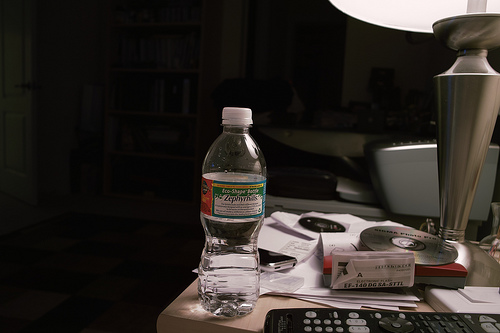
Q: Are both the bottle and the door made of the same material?
A: No, the bottle is made of plastic and the door is made of wood.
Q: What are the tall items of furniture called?
A: The pieces of furniture are shelves.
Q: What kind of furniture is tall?
A: The furniture is shelves.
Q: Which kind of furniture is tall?
A: The furniture is shelves.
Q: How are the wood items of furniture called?
A: The pieces of furniture are shelves.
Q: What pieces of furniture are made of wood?
A: The pieces of furniture are shelves.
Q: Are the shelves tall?
A: Yes, the shelves are tall.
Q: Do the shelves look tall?
A: Yes, the shelves are tall.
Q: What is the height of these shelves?
A: The shelves are tall.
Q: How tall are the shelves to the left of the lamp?
A: The shelves are tall.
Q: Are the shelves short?
A: No, the shelves are tall.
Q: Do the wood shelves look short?
A: No, the shelves are tall.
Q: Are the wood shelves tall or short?
A: The shelves are tall.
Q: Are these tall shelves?
A: Yes, these are tall shelves.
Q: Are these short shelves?
A: No, these are tall shelves.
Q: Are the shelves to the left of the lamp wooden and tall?
A: Yes, the shelves are wooden and tall.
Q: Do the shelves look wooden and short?
A: No, the shelves are wooden but tall.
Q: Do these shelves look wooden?
A: Yes, the shelves are wooden.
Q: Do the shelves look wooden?
A: Yes, the shelves are wooden.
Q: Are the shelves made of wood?
A: Yes, the shelves are made of wood.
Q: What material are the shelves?
A: The shelves are made of wood.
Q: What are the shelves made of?
A: The shelves are made of wood.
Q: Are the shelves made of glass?
A: No, the shelves are made of wood.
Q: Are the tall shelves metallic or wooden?
A: The shelves are wooden.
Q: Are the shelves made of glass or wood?
A: The shelves are made of wood.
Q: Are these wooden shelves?
A: Yes, these are wooden shelves.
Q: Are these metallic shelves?
A: No, these are wooden shelves.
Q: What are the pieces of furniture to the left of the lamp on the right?
A: The pieces of furniture are shelves.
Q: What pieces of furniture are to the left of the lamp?
A: The pieces of furniture are shelves.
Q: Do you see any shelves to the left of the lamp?
A: Yes, there are shelves to the left of the lamp.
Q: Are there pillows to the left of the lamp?
A: No, there are shelves to the left of the lamp.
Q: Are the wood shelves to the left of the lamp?
A: Yes, the shelves are to the left of the lamp.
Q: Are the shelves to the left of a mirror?
A: No, the shelves are to the left of the lamp.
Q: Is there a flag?
A: No, there are no flags.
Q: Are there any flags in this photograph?
A: No, there are no flags.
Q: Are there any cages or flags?
A: No, there are no flags or cages.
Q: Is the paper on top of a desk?
A: Yes, the paper is on top of a desk.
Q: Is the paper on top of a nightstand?
A: No, the paper is on top of a desk.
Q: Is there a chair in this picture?
A: No, there are no chairs.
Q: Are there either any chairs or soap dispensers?
A: No, there are no chairs or soap dispensers.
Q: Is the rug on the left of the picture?
A: Yes, the rug is on the left of the image.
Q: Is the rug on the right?
A: No, the rug is on the left of the image.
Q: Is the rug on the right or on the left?
A: The rug is on the left of the image.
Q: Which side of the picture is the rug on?
A: The rug is on the left of the image.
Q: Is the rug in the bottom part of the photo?
A: Yes, the rug is in the bottom of the image.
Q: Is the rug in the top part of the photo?
A: No, the rug is in the bottom of the image.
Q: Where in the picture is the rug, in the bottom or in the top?
A: The rug is in the bottom of the image.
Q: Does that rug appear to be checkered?
A: Yes, the rug is checkered.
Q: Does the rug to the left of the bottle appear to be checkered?
A: Yes, the rug is checkered.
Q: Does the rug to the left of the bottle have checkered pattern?
A: Yes, the rug is checkered.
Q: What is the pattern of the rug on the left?
A: The rug is checkered.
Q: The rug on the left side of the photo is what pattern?
A: The rug is checkered.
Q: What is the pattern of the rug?
A: The rug is checkered.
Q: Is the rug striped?
A: No, the rug is checkered.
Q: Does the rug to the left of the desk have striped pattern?
A: No, the rug is checkered.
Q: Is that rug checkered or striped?
A: The rug is checkered.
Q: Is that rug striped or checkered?
A: The rug is checkered.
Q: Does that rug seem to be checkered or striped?
A: The rug is checkered.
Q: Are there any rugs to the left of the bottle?
A: Yes, there is a rug to the left of the bottle.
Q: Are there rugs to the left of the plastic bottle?
A: Yes, there is a rug to the left of the bottle.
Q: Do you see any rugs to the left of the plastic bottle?
A: Yes, there is a rug to the left of the bottle.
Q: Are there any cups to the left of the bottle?
A: No, there is a rug to the left of the bottle.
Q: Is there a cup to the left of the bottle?
A: No, there is a rug to the left of the bottle.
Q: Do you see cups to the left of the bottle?
A: No, there is a rug to the left of the bottle.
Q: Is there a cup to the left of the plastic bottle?
A: No, there is a rug to the left of the bottle.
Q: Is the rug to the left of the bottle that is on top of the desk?
A: Yes, the rug is to the left of the bottle.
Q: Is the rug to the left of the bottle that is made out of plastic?
A: Yes, the rug is to the left of the bottle.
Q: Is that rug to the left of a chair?
A: No, the rug is to the left of the bottle.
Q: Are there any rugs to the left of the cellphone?
A: Yes, there is a rug to the left of the cellphone.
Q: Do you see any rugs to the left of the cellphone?
A: Yes, there is a rug to the left of the cellphone.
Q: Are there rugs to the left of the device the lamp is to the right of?
A: Yes, there is a rug to the left of the cellphone.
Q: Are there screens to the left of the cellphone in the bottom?
A: No, there is a rug to the left of the mobile phone.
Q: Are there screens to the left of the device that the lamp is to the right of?
A: No, there is a rug to the left of the mobile phone.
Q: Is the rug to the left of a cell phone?
A: Yes, the rug is to the left of a cell phone.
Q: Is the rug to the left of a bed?
A: No, the rug is to the left of a cell phone.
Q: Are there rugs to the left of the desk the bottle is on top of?
A: Yes, there is a rug to the left of the desk.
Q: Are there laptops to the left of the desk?
A: No, there is a rug to the left of the desk.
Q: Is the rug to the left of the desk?
A: Yes, the rug is to the left of the desk.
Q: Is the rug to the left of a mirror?
A: No, the rug is to the left of the desk.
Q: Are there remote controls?
A: Yes, there is a remote control.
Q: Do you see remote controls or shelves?
A: Yes, there is a remote control.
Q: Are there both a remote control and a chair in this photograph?
A: No, there is a remote control but no chairs.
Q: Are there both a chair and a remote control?
A: No, there is a remote control but no chairs.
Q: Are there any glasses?
A: No, there are no glasses.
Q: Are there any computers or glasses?
A: No, there are no glasses or computers.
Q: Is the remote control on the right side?
A: Yes, the remote control is on the right of the image.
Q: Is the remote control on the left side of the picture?
A: No, the remote control is on the right of the image.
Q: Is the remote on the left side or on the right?
A: The remote is on the right of the image.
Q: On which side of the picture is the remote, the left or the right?
A: The remote is on the right of the image.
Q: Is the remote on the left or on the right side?
A: The remote is on the right of the image.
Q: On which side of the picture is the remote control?
A: The remote control is on the right of the image.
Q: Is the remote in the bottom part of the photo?
A: Yes, the remote is in the bottom of the image.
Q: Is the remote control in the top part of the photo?
A: No, the remote control is in the bottom of the image.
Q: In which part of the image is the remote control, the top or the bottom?
A: The remote control is in the bottom of the image.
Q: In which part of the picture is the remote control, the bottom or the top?
A: The remote control is in the bottom of the image.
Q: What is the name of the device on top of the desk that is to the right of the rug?
A: The device is a remote control.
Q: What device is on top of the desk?
A: The device is a remote control.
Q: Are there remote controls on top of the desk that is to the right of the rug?
A: Yes, there is a remote control on top of the desk.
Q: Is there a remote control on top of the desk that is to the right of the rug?
A: Yes, there is a remote control on top of the desk.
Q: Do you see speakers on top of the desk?
A: No, there is a remote control on top of the desk.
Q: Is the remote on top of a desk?
A: Yes, the remote is on top of a desk.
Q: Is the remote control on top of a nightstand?
A: No, the remote control is on top of a desk.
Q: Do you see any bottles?
A: Yes, there is a bottle.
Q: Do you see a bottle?
A: Yes, there is a bottle.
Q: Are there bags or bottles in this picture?
A: Yes, there is a bottle.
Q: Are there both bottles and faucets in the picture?
A: No, there is a bottle but no faucets.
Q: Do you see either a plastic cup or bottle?
A: Yes, there is a plastic bottle.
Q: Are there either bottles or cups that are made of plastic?
A: Yes, the bottle is made of plastic.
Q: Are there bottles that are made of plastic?
A: Yes, there is a bottle that is made of plastic.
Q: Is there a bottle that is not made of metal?
A: Yes, there is a bottle that is made of plastic.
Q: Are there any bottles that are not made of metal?
A: Yes, there is a bottle that is made of plastic.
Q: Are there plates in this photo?
A: No, there are no plates.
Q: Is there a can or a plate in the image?
A: No, there are no plates or cans.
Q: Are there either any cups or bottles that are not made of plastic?
A: No, there is a bottle but it is made of plastic.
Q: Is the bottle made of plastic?
A: Yes, the bottle is made of plastic.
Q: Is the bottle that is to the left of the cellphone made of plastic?
A: Yes, the bottle is made of plastic.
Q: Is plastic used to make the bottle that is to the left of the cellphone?
A: Yes, the bottle is made of plastic.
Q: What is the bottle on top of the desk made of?
A: The bottle is made of plastic.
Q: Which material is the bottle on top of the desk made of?
A: The bottle is made of plastic.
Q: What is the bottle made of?
A: The bottle is made of plastic.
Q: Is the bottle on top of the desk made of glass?
A: No, the bottle is made of plastic.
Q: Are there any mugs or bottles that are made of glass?
A: No, there is a bottle but it is made of plastic.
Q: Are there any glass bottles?
A: No, there is a bottle but it is made of plastic.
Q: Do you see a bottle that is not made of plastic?
A: No, there is a bottle but it is made of plastic.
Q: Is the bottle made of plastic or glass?
A: The bottle is made of plastic.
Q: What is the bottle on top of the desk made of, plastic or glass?
A: The bottle is made of plastic.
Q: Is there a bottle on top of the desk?
A: Yes, there is a bottle on top of the desk.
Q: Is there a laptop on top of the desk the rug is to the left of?
A: No, there is a bottle on top of the desk.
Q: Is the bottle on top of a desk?
A: Yes, the bottle is on top of a desk.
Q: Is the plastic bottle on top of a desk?
A: Yes, the bottle is on top of a desk.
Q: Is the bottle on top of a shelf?
A: No, the bottle is on top of a desk.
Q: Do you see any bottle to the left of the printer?
A: Yes, there is a bottle to the left of the printer.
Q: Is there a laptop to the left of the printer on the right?
A: No, there is a bottle to the left of the printer.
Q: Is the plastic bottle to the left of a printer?
A: Yes, the bottle is to the left of a printer.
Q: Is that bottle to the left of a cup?
A: No, the bottle is to the left of a printer.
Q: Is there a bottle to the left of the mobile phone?
A: Yes, there is a bottle to the left of the mobile phone.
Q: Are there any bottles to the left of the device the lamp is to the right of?
A: Yes, there is a bottle to the left of the mobile phone.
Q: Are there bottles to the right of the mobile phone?
A: No, the bottle is to the left of the mobile phone.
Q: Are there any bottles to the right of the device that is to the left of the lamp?
A: No, the bottle is to the left of the mobile phone.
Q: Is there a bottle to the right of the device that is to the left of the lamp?
A: No, the bottle is to the left of the mobile phone.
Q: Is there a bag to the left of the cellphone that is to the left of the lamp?
A: No, there is a bottle to the left of the cell phone.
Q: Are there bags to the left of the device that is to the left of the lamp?
A: No, there is a bottle to the left of the cell phone.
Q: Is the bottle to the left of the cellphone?
A: Yes, the bottle is to the left of the cellphone.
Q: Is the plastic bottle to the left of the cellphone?
A: Yes, the bottle is to the left of the cellphone.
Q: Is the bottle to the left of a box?
A: No, the bottle is to the left of the cellphone.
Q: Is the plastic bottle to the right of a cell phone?
A: No, the bottle is to the left of a cell phone.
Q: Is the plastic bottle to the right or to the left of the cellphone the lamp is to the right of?
A: The bottle is to the left of the mobile phone.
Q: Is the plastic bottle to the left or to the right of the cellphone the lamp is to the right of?
A: The bottle is to the left of the mobile phone.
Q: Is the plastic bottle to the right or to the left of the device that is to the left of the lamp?
A: The bottle is to the left of the mobile phone.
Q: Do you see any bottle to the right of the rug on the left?
A: Yes, there is a bottle to the right of the rug.